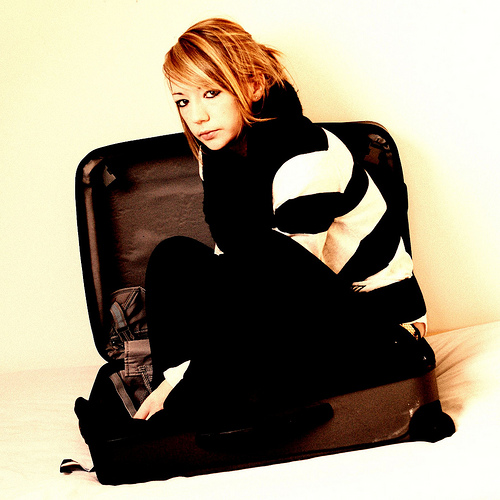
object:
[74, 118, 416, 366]
lid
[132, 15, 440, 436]
girl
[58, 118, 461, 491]
suitcase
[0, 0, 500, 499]
room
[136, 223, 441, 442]
pants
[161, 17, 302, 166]
red hair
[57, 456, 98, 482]
tags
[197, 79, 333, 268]
scarf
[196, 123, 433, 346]
sweater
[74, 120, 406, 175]
top of suitcase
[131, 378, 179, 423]
hand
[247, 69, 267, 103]
left ear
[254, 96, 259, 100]
earring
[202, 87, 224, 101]
eyes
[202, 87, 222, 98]
eyeliner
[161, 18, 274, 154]
head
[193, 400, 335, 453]
handle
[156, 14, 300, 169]
highlights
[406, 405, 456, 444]
wheel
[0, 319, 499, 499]
bed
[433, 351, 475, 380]
wrinkles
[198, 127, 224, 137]
lips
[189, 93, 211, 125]
nose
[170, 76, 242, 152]
face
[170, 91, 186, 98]
eyebrow